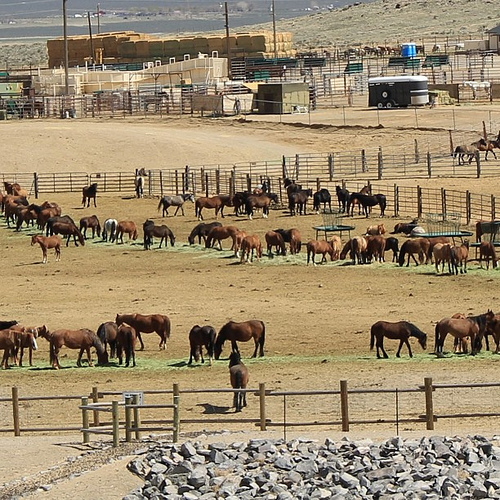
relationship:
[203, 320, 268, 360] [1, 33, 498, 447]
horse in pen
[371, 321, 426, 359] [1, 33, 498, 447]
horse in pen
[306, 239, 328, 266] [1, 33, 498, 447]
brown horse in pen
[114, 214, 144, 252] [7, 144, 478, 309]
brown horse in pen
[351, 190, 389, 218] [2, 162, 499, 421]
horse in pen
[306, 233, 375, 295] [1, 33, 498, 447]
horse in pen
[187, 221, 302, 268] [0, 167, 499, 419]
horses in corral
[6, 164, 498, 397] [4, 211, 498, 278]
horses eating grass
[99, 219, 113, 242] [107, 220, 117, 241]
horse has a tail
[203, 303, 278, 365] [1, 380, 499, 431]
horse next to fence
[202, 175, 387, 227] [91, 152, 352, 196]
horses next to fence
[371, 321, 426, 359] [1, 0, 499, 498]
horse in farm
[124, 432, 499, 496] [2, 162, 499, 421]
rocks in front of pen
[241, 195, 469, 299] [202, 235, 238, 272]
horses eating grass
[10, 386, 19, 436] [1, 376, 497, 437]
pole on fence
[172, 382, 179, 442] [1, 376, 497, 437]
pole on fence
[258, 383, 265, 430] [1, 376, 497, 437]
pole on fence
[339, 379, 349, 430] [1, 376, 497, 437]
pole on fence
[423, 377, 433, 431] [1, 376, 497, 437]
pole on fence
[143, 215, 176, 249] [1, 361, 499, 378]
horses eating grass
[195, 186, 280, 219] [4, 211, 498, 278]
horses eating grass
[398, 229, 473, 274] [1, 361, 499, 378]
horses eating grass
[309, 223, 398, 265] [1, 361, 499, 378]
horses eating grass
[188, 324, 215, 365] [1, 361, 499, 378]
horse eating grass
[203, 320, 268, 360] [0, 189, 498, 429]
horse in pen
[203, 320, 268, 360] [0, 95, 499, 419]
horse in corral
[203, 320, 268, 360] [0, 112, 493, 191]
horse in pen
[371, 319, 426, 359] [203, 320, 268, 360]
horse in horse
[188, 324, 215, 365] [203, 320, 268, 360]
horse in horse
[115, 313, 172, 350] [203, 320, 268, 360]
horse in horse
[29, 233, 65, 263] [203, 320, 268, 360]
horse in horse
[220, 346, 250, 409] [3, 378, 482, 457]
horse in fence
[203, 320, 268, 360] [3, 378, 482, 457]
horse in fence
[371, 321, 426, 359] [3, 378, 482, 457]
horse in fence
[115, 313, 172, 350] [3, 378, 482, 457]
horse in fence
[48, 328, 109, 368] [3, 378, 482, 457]
horse in fence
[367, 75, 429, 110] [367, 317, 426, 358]
horse trailer for transporting horses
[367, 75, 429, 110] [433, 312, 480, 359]
horse trailer for transporting horses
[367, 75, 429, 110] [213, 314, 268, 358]
horse trailer for transporting horses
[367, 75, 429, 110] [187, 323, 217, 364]
horse trailer for transporting horses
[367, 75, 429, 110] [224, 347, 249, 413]
horse trailer for transporting horses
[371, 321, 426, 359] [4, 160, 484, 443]
horse in fence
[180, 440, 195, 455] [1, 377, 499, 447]
rock outside fence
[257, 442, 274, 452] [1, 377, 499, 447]
rock outside fence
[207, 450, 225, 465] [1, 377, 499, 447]
rock outside fence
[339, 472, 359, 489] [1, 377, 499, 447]
rock outside fence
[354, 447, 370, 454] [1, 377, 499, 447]
rock outside fence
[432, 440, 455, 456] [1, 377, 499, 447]
rock outside fence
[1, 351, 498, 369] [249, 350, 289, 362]
grass on ground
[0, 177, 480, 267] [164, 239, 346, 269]
horses eating hay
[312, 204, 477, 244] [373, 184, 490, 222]
feed holders in fence